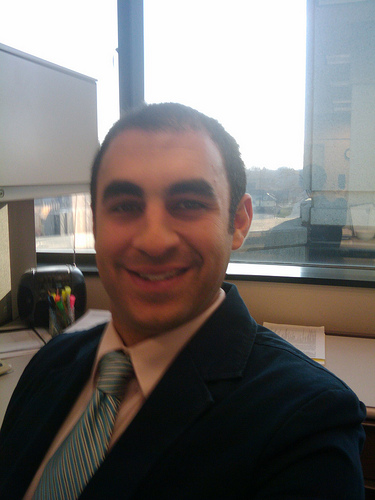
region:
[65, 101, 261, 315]
the man is smiling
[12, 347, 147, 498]
man's tie is striped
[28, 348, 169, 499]
the tie is blue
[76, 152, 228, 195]
man's eyebrows are black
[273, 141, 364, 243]
reflection in the window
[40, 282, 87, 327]
pens in the cup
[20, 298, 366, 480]
man's jacket is black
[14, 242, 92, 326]
the object is black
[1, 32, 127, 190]
the cabinet is white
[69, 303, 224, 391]
man's shirt is white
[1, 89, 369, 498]
a man in a suit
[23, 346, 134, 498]
a blue pin stripped tie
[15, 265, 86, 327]
a small black radio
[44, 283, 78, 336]
a cup of pens and highlighters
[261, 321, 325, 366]
a stack of paperwork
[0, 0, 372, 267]
a clear window to outside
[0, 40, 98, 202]
an overhead cabinet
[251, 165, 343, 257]
a reflection of the man in the window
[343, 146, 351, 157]
reflection of a clock in the window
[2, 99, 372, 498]
a man smiling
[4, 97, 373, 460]
a man in his office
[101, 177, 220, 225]
man has thick eyebrows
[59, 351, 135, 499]
man's tie is stripes of blue, white and gold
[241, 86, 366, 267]
cityscape outside office window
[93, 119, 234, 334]
man is smiling for the camera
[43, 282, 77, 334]
cup with many pens on the desk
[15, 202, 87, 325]
small radio on the desk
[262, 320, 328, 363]
pile of reports on desk behind man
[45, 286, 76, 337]
several highlighters in cup of pens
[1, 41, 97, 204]
lockable storage above the desk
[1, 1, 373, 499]
man sitting in front of window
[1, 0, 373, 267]
window in office building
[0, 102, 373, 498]
smiling man in suit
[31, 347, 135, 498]
blue and gray tie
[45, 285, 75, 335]
cup full of supplies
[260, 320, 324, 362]
stack of papers on desk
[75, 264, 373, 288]
empty black window ledge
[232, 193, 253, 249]
man's ear on right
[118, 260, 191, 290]
man smile showing teeth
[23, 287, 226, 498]
pale pink dress shirt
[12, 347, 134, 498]
a man's striped tie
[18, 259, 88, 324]
a tall black radio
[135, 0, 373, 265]
part of a large window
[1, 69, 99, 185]
part of a cabinet door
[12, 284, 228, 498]
a portion of a man's white shirt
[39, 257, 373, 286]
a dark window sill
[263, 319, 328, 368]
a white piece of paper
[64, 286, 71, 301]
a yellow highlighter pen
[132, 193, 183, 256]
the nose of a man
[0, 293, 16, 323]
a dark shadow